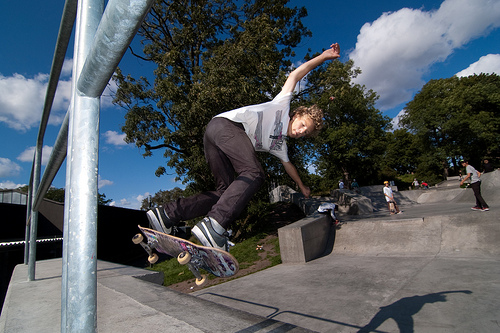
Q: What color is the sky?
A: Blue.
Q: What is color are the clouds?
A: White.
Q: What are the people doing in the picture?
A: Skateboarding.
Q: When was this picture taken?
A: During the day.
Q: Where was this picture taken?
A: At a skateboard park.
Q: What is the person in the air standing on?
A: A skateboard.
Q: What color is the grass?
A: Green.